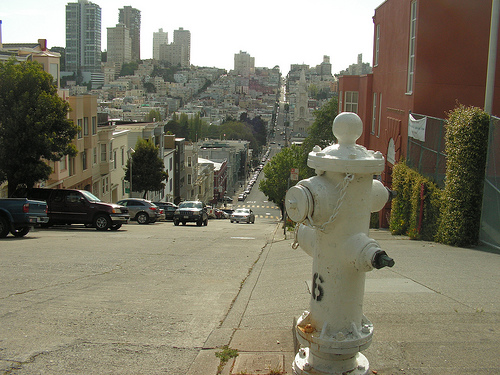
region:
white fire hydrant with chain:
[286, 110, 395, 373]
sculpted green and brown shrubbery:
[378, 103, 489, 248]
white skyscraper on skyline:
[60, 0, 110, 79]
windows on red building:
[398, 2, 424, 102]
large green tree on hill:
[0, 62, 80, 192]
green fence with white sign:
[400, 109, 449, 189]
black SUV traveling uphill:
[171, 199, 209, 229]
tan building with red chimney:
[26, 34, 103, 190]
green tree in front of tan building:
[1, 53, 98, 193]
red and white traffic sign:
[283, 155, 305, 184]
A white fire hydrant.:
[283, 111, 395, 373]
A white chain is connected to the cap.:
[285, 171, 354, 231]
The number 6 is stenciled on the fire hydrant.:
[310, 272, 326, 303]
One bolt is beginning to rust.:
[298, 315, 320, 340]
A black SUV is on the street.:
[172, 200, 208, 225]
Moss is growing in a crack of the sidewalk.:
[212, 343, 241, 365]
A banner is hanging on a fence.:
[405, 113, 427, 143]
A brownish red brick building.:
[335, 0, 498, 244]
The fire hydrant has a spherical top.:
[306, 111, 386, 171]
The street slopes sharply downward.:
[0, 197, 498, 374]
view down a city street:
[0, 181, 284, 373]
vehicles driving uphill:
[164, 196, 256, 247]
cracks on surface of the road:
[0, 259, 130, 371]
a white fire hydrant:
[282, 109, 392, 374]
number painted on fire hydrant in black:
[307, 268, 324, 303]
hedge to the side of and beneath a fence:
[388, 105, 485, 236]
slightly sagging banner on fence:
[403, 110, 428, 142]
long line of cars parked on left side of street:
[236, 101, 279, 205]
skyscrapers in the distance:
[63, 1, 190, 87]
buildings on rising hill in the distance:
[141, 23, 333, 110]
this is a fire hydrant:
[265, 110, 397, 373]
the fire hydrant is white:
[281, 99, 393, 372]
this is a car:
[218, 200, 264, 236]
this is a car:
[173, 198, 209, 235]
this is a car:
[153, 187, 188, 235]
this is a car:
[106, 178, 161, 232]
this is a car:
[27, 183, 130, 245]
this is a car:
[2, 179, 46, 244]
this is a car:
[233, 187, 251, 205]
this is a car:
[243, 183, 256, 200]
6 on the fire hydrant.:
[303, 267, 338, 307]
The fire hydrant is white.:
[253, 118, 405, 373]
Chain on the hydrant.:
[287, 166, 369, 237]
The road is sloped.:
[10, 135, 477, 373]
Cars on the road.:
[158, 182, 278, 244]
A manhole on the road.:
[220, 218, 267, 261]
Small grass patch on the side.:
[188, 337, 253, 374]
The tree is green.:
[1, 59, 66, 211]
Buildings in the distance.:
[69, 4, 340, 143]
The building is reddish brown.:
[329, 3, 474, 175]